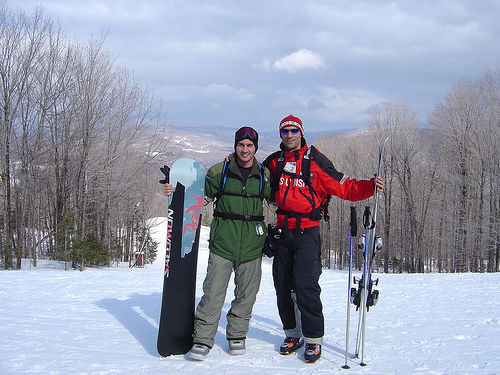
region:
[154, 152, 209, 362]
bottom side of a snowboard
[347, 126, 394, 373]
a pair of skis and ski poles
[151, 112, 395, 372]
two men doing winter sports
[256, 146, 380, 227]
man wearing a red ski jacket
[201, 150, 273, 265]
man wearing a green ski jacket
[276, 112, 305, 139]
man wearing a red hat with sunglasses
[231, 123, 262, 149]
man wearing a black hat with ski goggles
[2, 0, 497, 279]
barren trees in winter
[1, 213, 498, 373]
bright white snow on ground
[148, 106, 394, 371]
two men posing with their sports equipment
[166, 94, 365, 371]
Two people stanidng on the snow.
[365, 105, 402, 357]
A man is holding skis in his hand.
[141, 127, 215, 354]
A man is holding a snowboard.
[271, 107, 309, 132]
The man is wearing a red cap.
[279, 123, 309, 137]
The man is wearing blue sunglasses.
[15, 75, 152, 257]
Trees with no leaves on them.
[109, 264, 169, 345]
Reflection in the snow.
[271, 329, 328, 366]
Man is wearing black ski boots.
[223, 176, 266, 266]
A green jacket in the photo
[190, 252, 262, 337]
Gray trousers in the photo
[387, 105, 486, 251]
Trees at the back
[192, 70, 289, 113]
Clouds in the skies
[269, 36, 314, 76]
White clouds in the photo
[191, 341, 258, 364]
Blue and gray shoes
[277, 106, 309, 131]
A white and red hat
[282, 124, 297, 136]
Goggles in the photo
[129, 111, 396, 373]
Two men standing on ski trail.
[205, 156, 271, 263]
Man dressed in green jacket.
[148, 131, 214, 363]
Man holding a snowboard.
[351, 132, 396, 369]
Man holding snow skis.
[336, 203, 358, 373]
Ski pole stuck in snow.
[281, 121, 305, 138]
Man wearing sunglasses over eyes.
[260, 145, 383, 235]
Man dressed in red jacket.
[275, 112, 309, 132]
Man wearing red wool cap.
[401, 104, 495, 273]
Bare trees growing along snow trail.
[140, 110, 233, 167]
Mountains rising in distance.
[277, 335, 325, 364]
this man is wearing black white and red boots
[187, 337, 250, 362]
this man is wearing gray and white boots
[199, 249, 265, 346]
this man is wearing gray pants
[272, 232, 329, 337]
this man is wearing gray and blue pants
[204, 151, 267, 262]
this man is wearing a green jacket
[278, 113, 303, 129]
this man is wearing a red and white hat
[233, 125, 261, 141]
this man is wearing a black hat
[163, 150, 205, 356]
this man is holding a gray black and red snowboard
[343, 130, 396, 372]
this man is holding silver and black skis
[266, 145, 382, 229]
jacket is worn by human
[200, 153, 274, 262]
jacket is worn by human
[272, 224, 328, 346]
pants are worn by human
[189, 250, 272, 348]
pants are worn by human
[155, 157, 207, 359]
snowboard is held by human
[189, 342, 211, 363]
boot is worn by human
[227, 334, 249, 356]
boot is worn by human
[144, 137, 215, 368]
black snowboard with blue on it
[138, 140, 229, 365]
black snowboard with blue on it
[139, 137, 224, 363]
black snowboard with blue on it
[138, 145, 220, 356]
black snowboard with blue on it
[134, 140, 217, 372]
black snowboard with blue on it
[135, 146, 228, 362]
black snowboard with blue on it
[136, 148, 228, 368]
black snowboard with blue on it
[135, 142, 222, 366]
black snowboard with blue on it